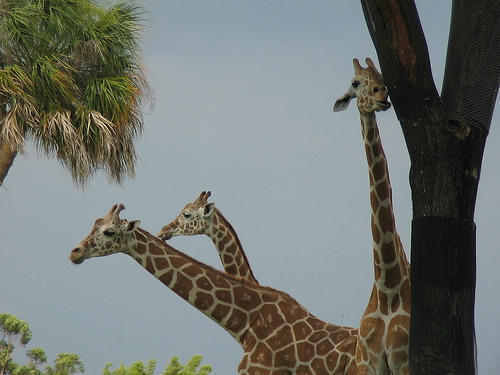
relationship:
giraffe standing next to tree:
[331, 57, 410, 374] [366, 12, 488, 374]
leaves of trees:
[1, 307, 57, 374] [0, 1, 498, 372]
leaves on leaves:
[0, 0, 148, 188] [0, 0, 148, 188]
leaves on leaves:
[1, 308, 212, 373] [1, 307, 57, 374]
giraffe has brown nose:
[69, 202, 364, 373] [69, 248, 79, 263]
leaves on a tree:
[0, 0, 148, 188] [4, 3, 140, 198]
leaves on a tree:
[2, 0, 148, 163] [0, 142, 25, 206]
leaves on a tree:
[1, 307, 60, 374] [1, 2, 155, 191]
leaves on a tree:
[162, 353, 213, 373] [1, 1, 212, 192]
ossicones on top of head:
[106, 202, 131, 217] [53, 199, 153, 273]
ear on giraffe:
[110, 200, 127, 212] [69, 202, 364, 373]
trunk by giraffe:
[359, 0, 499, 373] [331, 53, 421, 371]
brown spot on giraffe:
[389, 291, 402, 315] [331, 52, 411, 373]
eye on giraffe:
[348, 78, 363, 90] [152, 186, 266, 284]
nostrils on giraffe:
[73, 245, 82, 253] [69, 202, 364, 373]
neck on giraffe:
[355, 113, 406, 267] [331, 52, 411, 373]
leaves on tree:
[0, 0, 148, 188] [0, 22, 51, 184]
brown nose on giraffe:
[69, 248, 83, 255] [69, 202, 364, 373]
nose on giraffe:
[155, 226, 169, 243] [158, 181, 276, 359]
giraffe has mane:
[69, 202, 364, 373] [137, 225, 287, 295]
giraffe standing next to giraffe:
[331, 52, 411, 373] [155, 190, 260, 374]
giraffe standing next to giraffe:
[331, 52, 411, 373] [69, 202, 364, 373]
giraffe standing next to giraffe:
[155, 190, 260, 374] [331, 52, 411, 373]